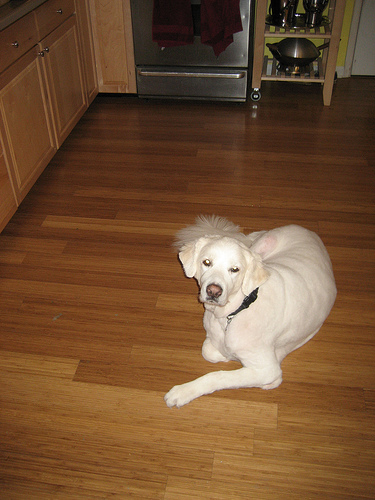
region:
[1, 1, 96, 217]
knobs on wooden drawers over wooden cabinets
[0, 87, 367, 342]
wooden floor composed of narrow boards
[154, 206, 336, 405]
big white dog laying on floor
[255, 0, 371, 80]
yellow wall with white trim next to panel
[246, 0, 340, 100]
wooden rack with wooden shelves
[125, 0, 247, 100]
brown towel hanging from metal oven door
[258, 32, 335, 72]
handled wok with curved lid and metal base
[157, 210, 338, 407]
smooth fur ending in fluffy tail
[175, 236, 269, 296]
dark and reflective eyes between droppy ears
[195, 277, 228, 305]
big pink nose over small angled mouth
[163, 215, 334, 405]
White dog laying on wood floor.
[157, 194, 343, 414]
white dog sitting down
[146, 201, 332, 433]
white dog looking at the camera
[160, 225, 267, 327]
white dog wearing a black collar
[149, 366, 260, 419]
left paw on a white dog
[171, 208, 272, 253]
end of the tail on a white dog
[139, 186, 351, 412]
white dog sitting down on the floor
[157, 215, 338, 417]
dog sitting on a wooden floor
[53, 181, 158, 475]
dark and light brown wooden floor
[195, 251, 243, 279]
camera flash reflected on a dog's eyes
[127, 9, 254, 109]
the bottom of a stainless steel oven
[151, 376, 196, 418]
Dog has white paw.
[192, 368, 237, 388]
Dog has white leg.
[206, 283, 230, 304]
Dog has tan nose.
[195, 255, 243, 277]
Dog has dark eyes.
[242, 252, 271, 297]
Dog has white ear.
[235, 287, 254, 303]
Dog wearing black collar.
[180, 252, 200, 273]
Dog has white ear.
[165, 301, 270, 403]
Dog laying on wood floor.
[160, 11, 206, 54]
Red towel hanging on oven.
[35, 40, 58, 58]
Silver knobs on cupboards.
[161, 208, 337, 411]
A dog is white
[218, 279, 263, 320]
Black collar around dog's neck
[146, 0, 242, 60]
Two hanging towels are red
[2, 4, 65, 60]
Knobs on drawers and cabinets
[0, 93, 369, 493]
A dog sitting on the floor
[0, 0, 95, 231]
Wooden cabinets and drawers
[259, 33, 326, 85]
A pot on a shelf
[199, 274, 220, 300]
Black nose on a dog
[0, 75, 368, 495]
The floor is wooden and brown